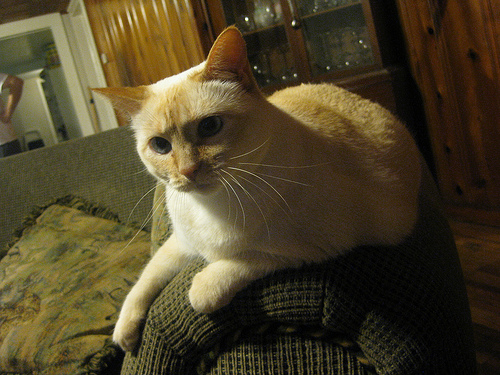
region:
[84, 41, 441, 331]
that is a cat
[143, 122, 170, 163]
that is the eye a cat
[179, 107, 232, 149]
that is the eye a cat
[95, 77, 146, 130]
that is the ear a cat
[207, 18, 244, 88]
that is the ear of a cat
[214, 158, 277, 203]
whiskers of the cat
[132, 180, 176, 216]
whiskers of the cat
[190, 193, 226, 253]
the fur of the cat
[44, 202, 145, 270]
that is a cushon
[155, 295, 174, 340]
the chair is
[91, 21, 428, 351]
pale orange cat with green eyes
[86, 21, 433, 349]
pale orange cat sitting on sofa arm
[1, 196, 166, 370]
green throw pillow with fringe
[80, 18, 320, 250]
face of orange cat with green eyes and white whiskers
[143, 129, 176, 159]
green cat eye on yellow cat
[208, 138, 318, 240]
spray of white cat whiskers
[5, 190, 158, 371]
tapestry style couch pillow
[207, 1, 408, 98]
china cabinet window with glasses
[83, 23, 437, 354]
yellow cat sitting on arm of green sofa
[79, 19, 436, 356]
yellow cat sitting on the edge of a couch arm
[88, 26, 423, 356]
Tan and white cat.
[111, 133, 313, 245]
Cat with white whiskers.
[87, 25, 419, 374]
Can lying on the arm of a sofa.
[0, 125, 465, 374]
A navy green sofa.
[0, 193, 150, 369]
A pillow lying on the sofa.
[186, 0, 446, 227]
Wooden cabinet behind the sofa.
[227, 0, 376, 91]
Glass cups inside of the cabinet.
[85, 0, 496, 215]
Wood paneled wall behind the cabinet.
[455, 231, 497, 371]
A hardwood floor.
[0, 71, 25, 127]
a person's arm and elbow.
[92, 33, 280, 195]
Cream colored cat's face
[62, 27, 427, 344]
Cream colored cat on arm of sofa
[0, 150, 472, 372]
Sofa holding cream colored cat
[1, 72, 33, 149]
Person with arm on hip in background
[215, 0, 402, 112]
China cabinet in background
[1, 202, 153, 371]
Pillow on sofa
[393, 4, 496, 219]
Golden wood paneled walls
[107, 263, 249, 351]
Paws of cream colored cat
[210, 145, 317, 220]
Whiskers of cream colored cat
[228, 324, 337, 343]
Braided rope in design of sofa